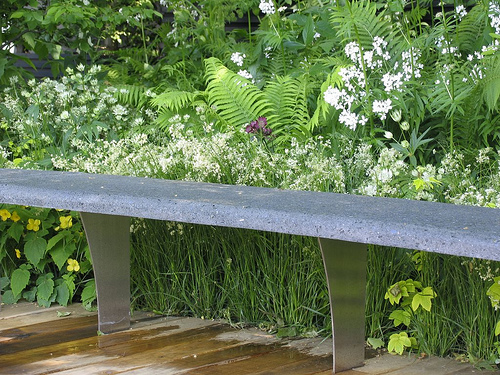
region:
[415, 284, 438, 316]
flower in the grass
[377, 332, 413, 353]
flower in the grass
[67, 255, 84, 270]
flower in the grass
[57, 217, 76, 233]
flower in the grass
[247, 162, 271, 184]
flower in the grass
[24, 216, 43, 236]
flower in the grass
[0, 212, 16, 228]
flower in the grass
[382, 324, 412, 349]
flowers in the grass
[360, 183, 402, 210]
flowers in the grass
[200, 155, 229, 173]
flowers in the grass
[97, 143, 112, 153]
flowers in the grass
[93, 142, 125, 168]
flowers in the grass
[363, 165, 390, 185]
flowers in the grass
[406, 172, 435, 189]
flowers in the grass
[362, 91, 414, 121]
Small white flower on stem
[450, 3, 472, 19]
Small white flower on stem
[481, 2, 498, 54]
Small white flower on stem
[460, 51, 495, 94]
Small white flower on stem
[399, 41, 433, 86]
Small white flower on stem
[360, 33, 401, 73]
Small white flower on stem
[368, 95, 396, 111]
Small white flower on stem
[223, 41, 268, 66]
Small white flower on stem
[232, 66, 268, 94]
Small white flower on stem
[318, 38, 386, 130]
Small white flower on stem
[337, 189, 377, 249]
area of grey bench to sit upon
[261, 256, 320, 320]
tall straight grass under bench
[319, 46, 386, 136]
white small flowers behind bench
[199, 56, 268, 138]
tall fern like plant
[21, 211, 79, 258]
small yellow flowers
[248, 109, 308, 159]
purple colored plant in middle of photo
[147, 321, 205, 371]
wet area of brown wood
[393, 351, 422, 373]
dry area of brown wood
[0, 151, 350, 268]
grey bench in front of photo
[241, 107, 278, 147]
A purple flower in a field.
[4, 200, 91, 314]
Yellow flowers growing under a bench.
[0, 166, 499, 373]
A gray colored bench in the park.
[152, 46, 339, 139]
A healthy fern plant growing.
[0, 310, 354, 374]
A puddle of water under the bench.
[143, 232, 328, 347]
Overgrown grass growing from the ground.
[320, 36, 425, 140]
The tops of white flowers.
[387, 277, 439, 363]
An ivy vine growing in the grass.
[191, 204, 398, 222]
Black specks of marble scattered int he bench.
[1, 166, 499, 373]
bench is concrete and metal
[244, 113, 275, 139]
flower is purple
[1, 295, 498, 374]
deck is wooden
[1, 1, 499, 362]
plants behind the bench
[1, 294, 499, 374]
wet spot on the deck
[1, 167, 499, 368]
metal legs on the bench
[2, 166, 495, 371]
concrete seat on the bench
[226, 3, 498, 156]
white flowers on the bush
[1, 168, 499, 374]
seat on the bench is gray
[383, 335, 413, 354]
a leaf on a stem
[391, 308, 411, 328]
a leaf on a stem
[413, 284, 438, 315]
a leaf on a stem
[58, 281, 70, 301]
a leaf on a stem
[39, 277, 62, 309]
a leaf on a stem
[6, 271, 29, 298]
a leaf on a stem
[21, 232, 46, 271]
a leaf on a stem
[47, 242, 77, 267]
a leaf on a stem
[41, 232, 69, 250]
a leaf on a stem